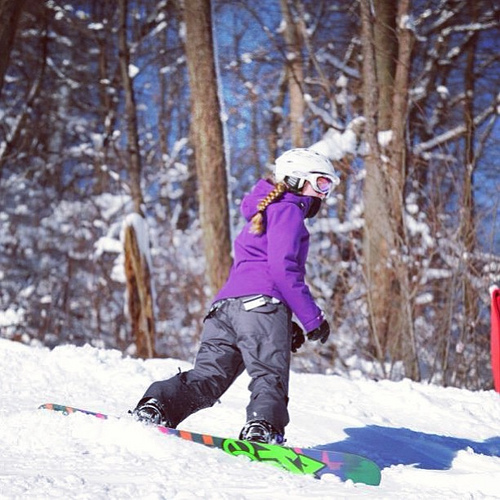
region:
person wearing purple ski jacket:
[132, 143, 340, 454]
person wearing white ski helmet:
[133, 145, 338, 449]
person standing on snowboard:
[133, 146, 334, 446]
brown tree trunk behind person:
[182, 0, 232, 290]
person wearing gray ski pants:
[132, 145, 340, 449]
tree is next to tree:
[356, 5, 417, 370]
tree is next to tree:
[461, 45, 481, 376]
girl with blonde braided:
[125, 150, 330, 440]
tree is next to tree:
[121, 220, 161, 357]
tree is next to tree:
[116, 16, 146, 220]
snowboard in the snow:
[33, 397, 392, 491]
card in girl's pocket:
[239, 288, 269, 315]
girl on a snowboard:
[115, 140, 340, 461]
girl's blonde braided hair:
[251, 177, 293, 237]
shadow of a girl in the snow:
[303, 414, 498, 480]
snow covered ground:
[1, 331, 499, 498]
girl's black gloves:
[287, 312, 334, 356]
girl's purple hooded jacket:
[214, 170, 326, 329]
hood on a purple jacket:
[235, 175, 315, 218]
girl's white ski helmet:
[271, 144, 346, 196]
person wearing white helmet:
[120, 148, 356, 461]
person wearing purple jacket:
[127, 130, 357, 455]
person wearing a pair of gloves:
[125, 128, 346, 466]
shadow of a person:
[285, 401, 497, 481]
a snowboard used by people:
[35, 390, 397, 492]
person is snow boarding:
[20, 136, 408, 493]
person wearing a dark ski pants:
[53, 116, 398, 491]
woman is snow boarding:
[25, 127, 400, 496]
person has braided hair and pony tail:
[34, 137, 400, 479]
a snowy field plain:
[47, 439, 172, 499]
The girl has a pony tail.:
[249, 181, 288, 246]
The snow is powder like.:
[18, 409, 149, 485]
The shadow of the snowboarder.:
[335, 406, 497, 476]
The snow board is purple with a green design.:
[173, 424, 387, 489]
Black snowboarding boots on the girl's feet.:
[141, 399, 286, 445]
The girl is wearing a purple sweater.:
[223, 165, 335, 335]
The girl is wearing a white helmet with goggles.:
[265, 131, 344, 194]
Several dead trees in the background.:
[360, 110, 488, 372]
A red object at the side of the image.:
[478, 280, 499, 396]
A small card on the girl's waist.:
[242, 293, 266, 311]